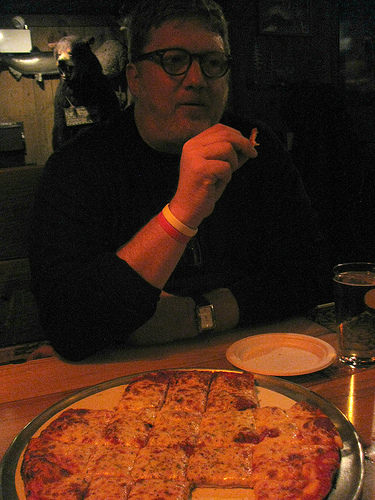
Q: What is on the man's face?
A: Glasses.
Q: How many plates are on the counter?
A: One.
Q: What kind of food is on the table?
A: Pizza.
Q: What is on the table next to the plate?
A: Glass of water.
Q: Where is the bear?
A: Behind the man.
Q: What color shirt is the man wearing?
A: Black.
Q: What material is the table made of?
A: Wood.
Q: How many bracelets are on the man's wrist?
A: Two.